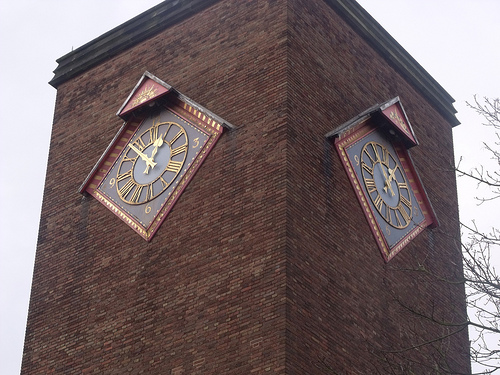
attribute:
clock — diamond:
[76, 68, 236, 241]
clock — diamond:
[322, 96, 437, 264]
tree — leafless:
[464, 94, 497, 311]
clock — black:
[321, 107, 446, 260]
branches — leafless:
[414, 87, 498, 372]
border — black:
[88, 25, 126, 60]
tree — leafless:
[385, 90, 499, 367]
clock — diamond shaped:
[15, 61, 279, 248]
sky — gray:
[400, 12, 476, 59]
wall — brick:
[48, 25, 494, 371]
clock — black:
[111, 116, 193, 211]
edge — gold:
[78, 70, 230, 242]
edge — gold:
[327, 97, 447, 259]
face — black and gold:
[109, 110, 190, 217]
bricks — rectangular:
[196, 31, 286, 373]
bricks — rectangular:
[40, 232, 230, 369]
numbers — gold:
[360, 139, 412, 229]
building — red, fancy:
[23, 1, 470, 373]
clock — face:
[360, 141, 412, 231]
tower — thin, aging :
[24, 0, 467, 372]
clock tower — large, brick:
[17, 0, 469, 374]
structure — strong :
[19, 8, 465, 370]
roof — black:
[37, 2, 467, 130]